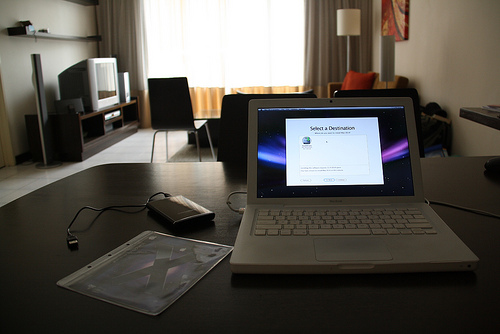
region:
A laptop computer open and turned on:
[236, 91, 471, 290]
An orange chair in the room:
[328, 72, 384, 86]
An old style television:
[63, 58, 124, 108]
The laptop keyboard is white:
[229, 194, 482, 268]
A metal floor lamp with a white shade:
[336, 4, 360, 71]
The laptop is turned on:
[248, 94, 421, 203]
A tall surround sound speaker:
[26, 44, 61, 166]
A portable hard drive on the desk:
[151, 178, 215, 231]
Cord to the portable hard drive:
[48, 195, 153, 254]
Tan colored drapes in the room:
[293, 0, 326, 77]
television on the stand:
[68, 54, 134, 114]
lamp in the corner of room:
[338, 8, 368, 60]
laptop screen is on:
[266, 123, 375, 170]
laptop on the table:
[289, 206, 362, 294]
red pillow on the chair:
[339, 67, 370, 87]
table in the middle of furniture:
[195, 102, 224, 137]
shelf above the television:
[55, 28, 80, 46]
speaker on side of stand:
[27, 58, 61, 122]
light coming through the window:
[188, 22, 260, 76]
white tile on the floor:
[129, 130, 150, 160]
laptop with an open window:
[228, 93, 485, 277]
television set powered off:
[56, 55, 123, 114]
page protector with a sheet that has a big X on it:
[53, 228, 235, 318]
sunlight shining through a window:
[146, 0, 304, 86]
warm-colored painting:
[378, 0, 408, 41]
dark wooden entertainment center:
[21, 100, 142, 160]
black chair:
[146, 76, 217, 166]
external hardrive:
[64, 188, 221, 246]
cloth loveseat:
[329, 75, 421, 146]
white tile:
[0, 126, 221, 208]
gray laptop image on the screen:
[226, 96, 483, 273]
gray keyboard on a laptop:
[250, 201, 439, 238]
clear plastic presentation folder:
[55, 225, 233, 325]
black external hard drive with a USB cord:
[59, 185, 227, 257]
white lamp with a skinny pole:
[331, 2, 363, 73]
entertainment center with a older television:
[14, 46, 144, 173]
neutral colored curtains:
[296, 0, 336, 98]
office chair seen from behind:
[140, 62, 218, 164]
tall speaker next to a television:
[23, 45, 122, 176]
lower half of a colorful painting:
[376, 2, 419, 53]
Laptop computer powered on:
[230, 93, 483, 270]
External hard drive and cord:
[64, 190, 216, 247]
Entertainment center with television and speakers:
[18, 54, 142, 169]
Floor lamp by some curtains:
[331, 7, 365, 75]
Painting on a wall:
[376, 0, 411, 42]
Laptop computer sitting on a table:
[227, 95, 482, 273]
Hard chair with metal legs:
[146, 74, 216, 161]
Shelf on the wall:
[3, 18, 100, 45]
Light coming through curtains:
[126, 0, 311, 89]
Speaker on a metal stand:
[21, 50, 58, 168]